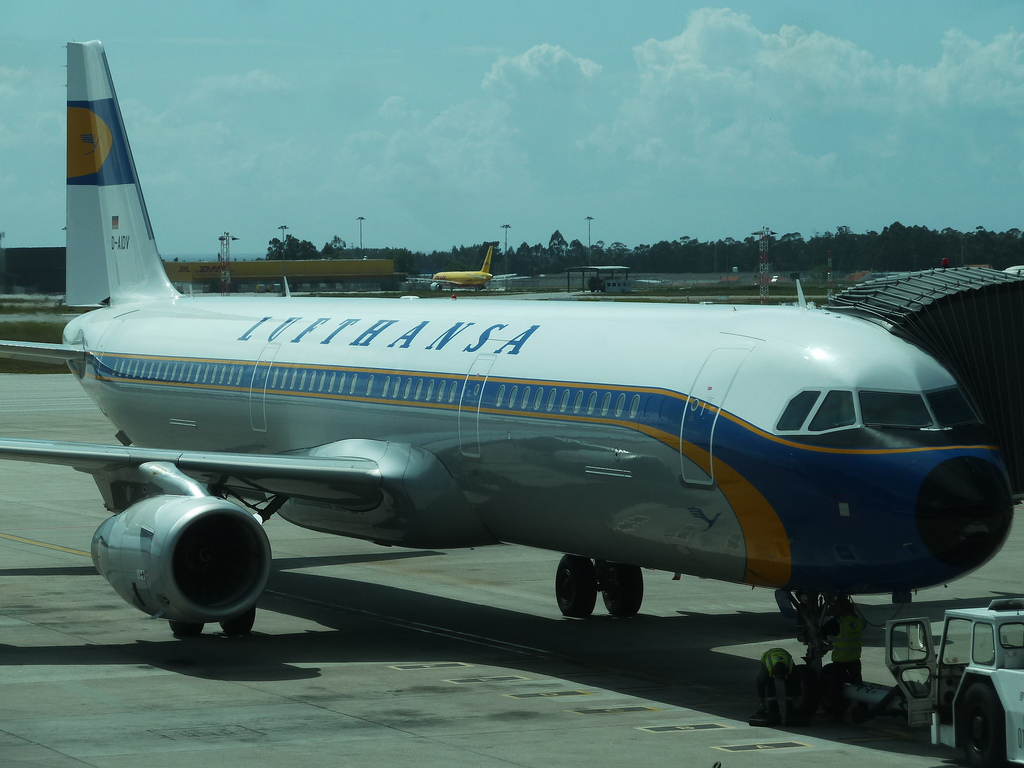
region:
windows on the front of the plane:
[768, 373, 985, 450]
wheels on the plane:
[551, 554, 651, 624]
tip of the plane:
[57, 29, 159, 315]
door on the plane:
[661, 328, 757, 510]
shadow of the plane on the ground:
[329, 556, 460, 670]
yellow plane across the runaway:
[421, 241, 507, 292]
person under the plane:
[751, 622, 808, 712]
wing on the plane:
[16, 423, 416, 497]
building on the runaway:
[236, 258, 388, 288]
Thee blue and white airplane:
[31, 23, 987, 726]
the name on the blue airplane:
[224, 314, 551, 369]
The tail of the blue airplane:
[40, 32, 189, 302]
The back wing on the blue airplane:
[2, 326, 94, 375]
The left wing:
[0, 428, 380, 499]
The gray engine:
[91, 500, 281, 625]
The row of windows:
[105, 346, 649, 441]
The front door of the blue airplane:
[665, 330, 745, 501]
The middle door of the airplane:
[450, 338, 508, 468]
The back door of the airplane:
[245, 338, 296, 437]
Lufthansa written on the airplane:
[228, 303, 570, 367]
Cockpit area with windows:
[773, 358, 999, 479]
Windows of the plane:
[76, 328, 675, 440]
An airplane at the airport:
[9, 28, 1022, 725]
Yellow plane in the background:
[426, 246, 515, 297]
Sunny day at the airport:
[16, 12, 1013, 736]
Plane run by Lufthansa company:
[9, 26, 1013, 761]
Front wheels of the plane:
[749, 571, 899, 709]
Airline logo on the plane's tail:
[46, 34, 187, 316]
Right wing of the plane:
[2, 414, 449, 516]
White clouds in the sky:
[1, 1, 1016, 271]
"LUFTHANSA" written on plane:
[225, 298, 545, 362]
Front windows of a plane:
[762, 370, 996, 446]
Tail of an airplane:
[45, 23, 198, 314]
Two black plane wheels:
[535, 535, 659, 631]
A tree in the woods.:
[549, 232, 569, 268]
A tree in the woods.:
[625, 245, 648, 271]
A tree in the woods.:
[647, 238, 671, 273]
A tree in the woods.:
[686, 242, 710, 278]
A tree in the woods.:
[711, 238, 734, 277]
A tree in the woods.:
[726, 236, 746, 272]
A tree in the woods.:
[771, 231, 803, 266]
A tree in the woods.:
[837, 223, 860, 271]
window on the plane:
[622, 389, 643, 422]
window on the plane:
[599, 385, 615, 421]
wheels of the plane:
[544, 544, 677, 643]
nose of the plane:
[740, 334, 1016, 595]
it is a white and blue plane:
[43, 28, 968, 766]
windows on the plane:
[142, 351, 447, 418]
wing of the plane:
[29, 417, 418, 651]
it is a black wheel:
[546, 556, 695, 626]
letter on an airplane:
[259, 303, 295, 346]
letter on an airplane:
[293, 312, 328, 348]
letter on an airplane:
[319, 309, 357, 361]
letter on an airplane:
[382, 310, 428, 358]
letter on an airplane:
[496, 318, 542, 364]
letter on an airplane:
[95, 230, 144, 256]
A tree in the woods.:
[299, 241, 313, 261]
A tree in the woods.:
[321, 229, 340, 259]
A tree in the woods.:
[448, 241, 471, 262]